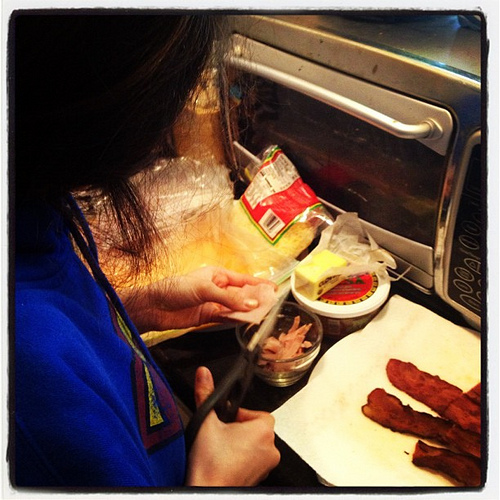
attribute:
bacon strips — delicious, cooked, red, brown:
[365, 359, 495, 483]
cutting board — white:
[276, 292, 500, 488]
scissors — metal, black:
[185, 283, 299, 443]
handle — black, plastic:
[178, 343, 268, 443]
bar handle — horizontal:
[226, 63, 434, 129]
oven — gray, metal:
[223, 14, 475, 248]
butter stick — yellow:
[306, 252, 341, 280]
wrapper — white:
[293, 221, 393, 293]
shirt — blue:
[24, 249, 177, 499]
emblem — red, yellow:
[109, 303, 192, 455]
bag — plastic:
[160, 144, 336, 275]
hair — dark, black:
[1, 2, 213, 275]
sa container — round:
[289, 255, 393, 331]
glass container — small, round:
[241, 307, 320, 393]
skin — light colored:
[221, 464, 254, 484]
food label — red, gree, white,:
[244, 161, 317, 239]